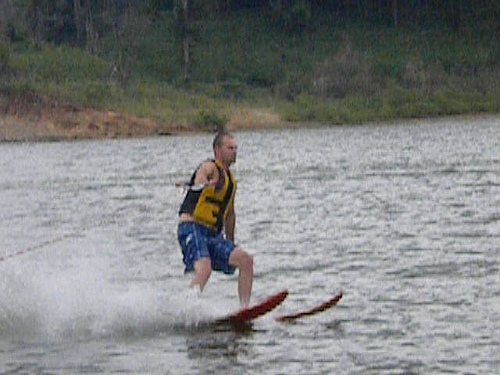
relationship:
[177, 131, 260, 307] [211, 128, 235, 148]
man has hair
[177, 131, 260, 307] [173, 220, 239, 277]
man has shorts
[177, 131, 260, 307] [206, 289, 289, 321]
man on skis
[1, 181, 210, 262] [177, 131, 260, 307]
cable next to man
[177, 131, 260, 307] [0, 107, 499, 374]
man on water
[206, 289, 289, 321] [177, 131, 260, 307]
skis are under man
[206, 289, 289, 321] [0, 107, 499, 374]
skis are on top of water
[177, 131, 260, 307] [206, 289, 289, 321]
man on top of skis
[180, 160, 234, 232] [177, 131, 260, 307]
life vest on man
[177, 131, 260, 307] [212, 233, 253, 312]
man has legs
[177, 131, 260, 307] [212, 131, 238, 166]
man has head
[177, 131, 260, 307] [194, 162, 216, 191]
man has arm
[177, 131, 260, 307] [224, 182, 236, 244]
man has other arm